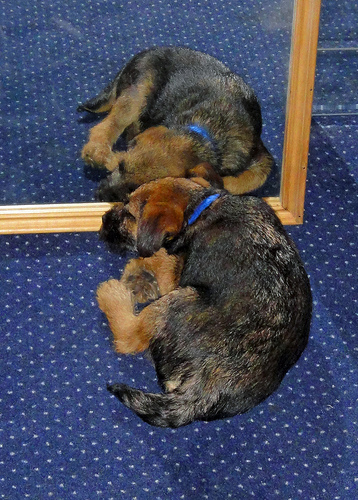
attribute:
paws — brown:
[98, 247, 178, 320]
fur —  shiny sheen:
[159, 193, 312, 412]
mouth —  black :
[100, 226, 120, 242]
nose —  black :
[101, 211, 110, 223]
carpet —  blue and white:
[3, 245, 85, 388]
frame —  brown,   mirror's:
[272, 11, 305, 215]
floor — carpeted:
[252, 417, 322, 498]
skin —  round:
[222, 145, 274, 197]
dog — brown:
[96, 176, 312, 426]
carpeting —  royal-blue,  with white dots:
[2, 0, 356, 497]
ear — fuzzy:
[136, 203, 189, 257]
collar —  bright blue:
[185, 190, 221, 228]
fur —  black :
[214, 218, 288, 300]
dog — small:
[102, 186, 306, 416]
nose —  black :
[100, 214, 109, 224]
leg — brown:
[93, 279, 142, 360]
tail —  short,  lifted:
[98, 376, 174, 431]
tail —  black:
[105, 376, 234, 429]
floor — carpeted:
[5, 3, 352, 497]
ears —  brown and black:
[132, 201, 183, 261]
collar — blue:
[187, 191, 217, 221]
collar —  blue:
[183, 191, 225, 223]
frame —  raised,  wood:
[289, 9, 315, 221]